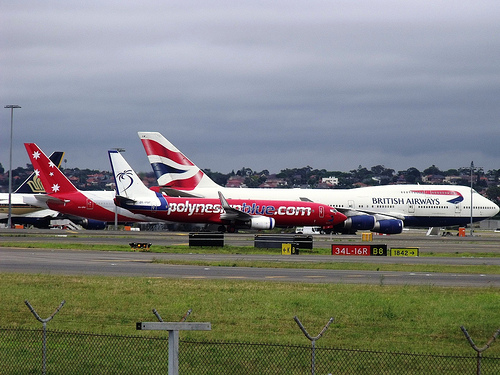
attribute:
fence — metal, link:
[2, 327, 498, 373]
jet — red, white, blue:
[108, 147, 348, 231]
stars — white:
[23, 141, 47, 166]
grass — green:
[1, 272, 498, 373]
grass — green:
[153, 253, 499, 272]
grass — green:
[0, 237, 497, 257]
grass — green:
[264, 288, 403, 323]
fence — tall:
[1, 293, 499, 373]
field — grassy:
[81, 284, 478, 348]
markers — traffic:
[329, 241, 419, 259]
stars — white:
[28, 150, 62, 193]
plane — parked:
[23, 142, 205, 225]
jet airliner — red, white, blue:
[95, 136, 392, 243]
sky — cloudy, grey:
[328, 46, 432, 103]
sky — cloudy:
[3, 3, 497, 208]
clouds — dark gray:
[87, 27, 362, 125]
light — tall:
[3, 102, 22, 109]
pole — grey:
[6, 107, 14, 227]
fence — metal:
[272, 346, 343, 373]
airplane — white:
[133, 127, 498, 244]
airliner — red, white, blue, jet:
[135, 126, 485, 238]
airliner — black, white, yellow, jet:
[24, 140, 173, 224]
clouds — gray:
[12, 11, 499, 130]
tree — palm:
[116, 167, 134, 197]